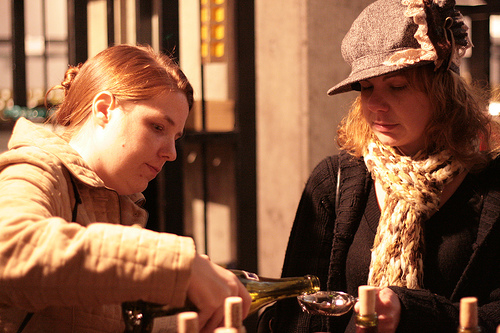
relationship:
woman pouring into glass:
[1, 43, 248, 330] [298, 283, 358, 330]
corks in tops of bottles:
[122, 253, 403, 330] [351, 321, 487, 331]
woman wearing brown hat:
[272, 1, 495, 331] [323, 2, 475, 93]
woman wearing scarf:
[272, 1, 495, 331] [350, 136, 476, 293]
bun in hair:
[60, 62, 80, 92] [46, 43, 190, 128]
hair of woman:
[46, 43, 190, 128] [1, 43, 248, 330]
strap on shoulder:
[330, 151, 345, 264] [281, 148, 373, 282]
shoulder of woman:
[281, 148, 373, 282] [272, 1, 495, 331]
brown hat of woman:
[326, 0, 468, 96] [272, 1, 495, 331]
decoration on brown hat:
[403, 0, 471, 63] [326, 0, 468, 96]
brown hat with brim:
[326, 0, 468, 96] [325, 52, 420, 96]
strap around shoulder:
[68, 182, 82, 221] [6, 147, 74, 179]